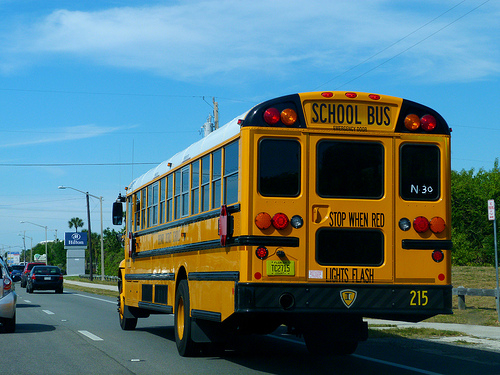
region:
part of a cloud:
[77, 7, 120, 60]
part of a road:
[106, 329, 134, 365]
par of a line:
[78, 316, 97, 348]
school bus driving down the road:
[114, 89, 454, 355]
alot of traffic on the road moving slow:
[0, 248, 64, 335]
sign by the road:
[65, 230, 88, 276]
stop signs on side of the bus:
[126, 205, 233, 250]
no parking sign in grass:
[486, 198, 498, 296]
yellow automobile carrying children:
[113, 89, 455, 357]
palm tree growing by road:
[66, 215, 85, 232]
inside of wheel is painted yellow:
[173, 276, 218, 356]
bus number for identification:
[406, 289, 433, 309]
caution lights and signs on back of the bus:
[253, 88, 450, 308]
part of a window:
[271, 148, 299, 185]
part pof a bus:
[278, 230, 323, 296]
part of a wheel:
[170, 319, 192, 371]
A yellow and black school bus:
[109, 85, 458, 365]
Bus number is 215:
[400, 279, 435, 314]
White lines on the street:
[9, 283, 108, 346]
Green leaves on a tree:
[443, 158, 498, 267]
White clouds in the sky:
[2, 0, 499, 251]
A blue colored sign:
[60, 228, 91, 250]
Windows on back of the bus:
[255, 130, 443, 269]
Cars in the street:
[0, 252, 66, 335]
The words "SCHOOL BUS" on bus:
[309, 91, 394, 128]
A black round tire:
[169, 273, 196, 360]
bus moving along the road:
[48, 22, 480, 357]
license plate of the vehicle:
[265, 252, 296, 277]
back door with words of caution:
[297, 125, 397, 287]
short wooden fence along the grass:
[451, 276, 496, 306]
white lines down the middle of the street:
[22, 295, 102, 347]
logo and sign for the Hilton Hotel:
[61, 226, 86, 271]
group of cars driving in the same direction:
[0, 225, 70, 340]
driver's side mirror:
[110, 190, 130, 230]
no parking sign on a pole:
[480, 192, 498, 269]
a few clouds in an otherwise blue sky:
[35, 35, 233, 91]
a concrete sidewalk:
[360, 312, 499, 354]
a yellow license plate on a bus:
[262, 255, 292, 275]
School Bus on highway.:
[98, 73, 470, 358]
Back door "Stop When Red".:
[307, 198, 398, 240]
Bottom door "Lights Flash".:
[306, 259, 391, 289]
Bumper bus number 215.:
[386, 258, 451, 325]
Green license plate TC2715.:
[258, 255, 305, 283]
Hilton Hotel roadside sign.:
[58, 228, 93, 280]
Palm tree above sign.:
[55, 211, 99, 233]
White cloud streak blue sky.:
[7, 100, 154, 162]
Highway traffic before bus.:
[9, 255, 80, 332]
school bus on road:
[112, 88, 451, 358]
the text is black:
[310, 100, 392, 124]